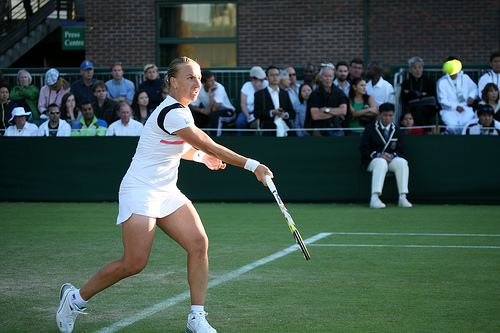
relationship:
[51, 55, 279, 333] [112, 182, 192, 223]
player wearing skirt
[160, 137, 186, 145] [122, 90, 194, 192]
strip on shirt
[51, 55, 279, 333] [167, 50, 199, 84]
player has hair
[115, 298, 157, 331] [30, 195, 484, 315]
line on court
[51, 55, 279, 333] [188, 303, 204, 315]
player wearing socks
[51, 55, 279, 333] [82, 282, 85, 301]
player wearing socks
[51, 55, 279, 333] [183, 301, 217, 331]
player wearing shoes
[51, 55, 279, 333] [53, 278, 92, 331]
player wearing shoes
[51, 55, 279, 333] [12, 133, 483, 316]
player playing tennis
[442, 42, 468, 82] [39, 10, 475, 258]
ball in air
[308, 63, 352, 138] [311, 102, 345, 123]
man standing with arms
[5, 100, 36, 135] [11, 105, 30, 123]
person in a hat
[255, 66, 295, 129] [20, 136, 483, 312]
person watching tennis match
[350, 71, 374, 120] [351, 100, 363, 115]
woman wearing a shirt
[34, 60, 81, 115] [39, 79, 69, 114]
person wearing shirt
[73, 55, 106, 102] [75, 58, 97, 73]
man wearing hat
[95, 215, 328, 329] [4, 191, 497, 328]
line on court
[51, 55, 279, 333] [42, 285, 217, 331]
player wearing shoes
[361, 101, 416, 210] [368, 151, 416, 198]
man wearing pants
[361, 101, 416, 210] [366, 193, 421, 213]
man wearing shoes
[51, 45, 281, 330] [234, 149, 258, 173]
player wearing band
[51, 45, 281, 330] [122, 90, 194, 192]
player wearing shirt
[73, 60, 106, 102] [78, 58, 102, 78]
man wearing hat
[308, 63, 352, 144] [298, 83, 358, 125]
man wearing shirt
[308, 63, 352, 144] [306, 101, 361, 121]
man with arms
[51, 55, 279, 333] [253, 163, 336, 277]
player holding racket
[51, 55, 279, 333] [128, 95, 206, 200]
player wearing shirt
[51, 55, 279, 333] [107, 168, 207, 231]
player wearing skirt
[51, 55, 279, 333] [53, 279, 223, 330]
player wearing shoes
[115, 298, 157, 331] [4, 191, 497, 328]
line on court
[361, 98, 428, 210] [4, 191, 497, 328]
man on side of court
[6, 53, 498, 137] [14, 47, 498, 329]
spectators watching match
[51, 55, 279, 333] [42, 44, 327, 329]
player playing tennis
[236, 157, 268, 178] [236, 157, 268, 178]
wristband on wristband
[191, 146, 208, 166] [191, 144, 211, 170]
wrist on wrist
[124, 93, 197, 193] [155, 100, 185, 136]
shirt with stripe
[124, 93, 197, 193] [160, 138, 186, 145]
shirt with strip